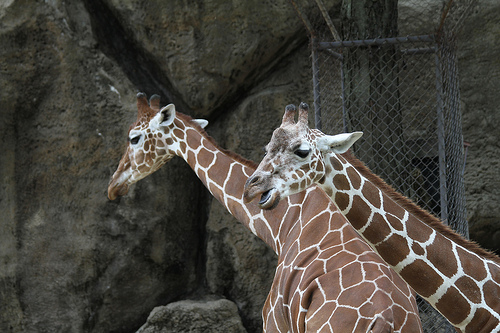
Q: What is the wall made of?
A: Rocks.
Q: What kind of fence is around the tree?
A: Chain link.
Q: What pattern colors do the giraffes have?
A: Brown and cream.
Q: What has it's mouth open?
A: Giraffe.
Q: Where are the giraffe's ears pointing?
A: To the side.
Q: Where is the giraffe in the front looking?
A: Down.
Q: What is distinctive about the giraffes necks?
A: Long.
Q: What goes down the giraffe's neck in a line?
A: Hair.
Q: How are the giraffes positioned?
A: Standing up.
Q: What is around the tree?
A: Fence.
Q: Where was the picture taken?
A: Zoo.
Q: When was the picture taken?
A: During the daytime.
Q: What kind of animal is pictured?
A: Giraffe.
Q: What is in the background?
A: Stone wall.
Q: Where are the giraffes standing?
A: Next to each other.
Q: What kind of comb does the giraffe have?
A: Brown.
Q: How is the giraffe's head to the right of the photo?
A: Resting on another giraffe's lower neck.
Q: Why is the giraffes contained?
A: Wild animals.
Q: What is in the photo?
A: Two giraffes.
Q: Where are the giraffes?
A: Zoo.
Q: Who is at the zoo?
A: Family with children.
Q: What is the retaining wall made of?
A: Stones.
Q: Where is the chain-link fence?
A: Around the tree.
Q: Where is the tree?
A: Inside the fence.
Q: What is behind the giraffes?
A: A fence.